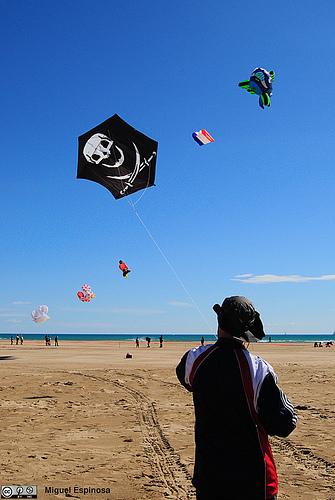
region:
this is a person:
[133, 262, 321, 498]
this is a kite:
[48, 95, 183, 219]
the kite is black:
[60, 93, 180, 217]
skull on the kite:
[65, 128, 141, 174]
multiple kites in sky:
[0, 13, 314, 366]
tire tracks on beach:
[63, 335, 331, 495]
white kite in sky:
[23, 292, 64, 329]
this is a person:
[154, 281, 318, 497]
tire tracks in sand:
[59, 354, 327, 497]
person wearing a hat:
[205, 274, 287, 359]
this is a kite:
[52, 90, 197, 240]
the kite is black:
[42, 97, 198, 236]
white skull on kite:
[77, 129, 127, 172]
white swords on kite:
[101, 136, 161, 194]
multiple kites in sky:
[32, 45, 306, 377]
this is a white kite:
[21, 296, 75, 351]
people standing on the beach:
[18, 319, 193, 360]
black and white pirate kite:
[76, 111, 159, 199]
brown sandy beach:
[0, 337, 333, 498]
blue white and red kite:
[190, 128, 214, 145]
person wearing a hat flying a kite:
[174, 294, 296, 498]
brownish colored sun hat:
[212, 294, 266, 343]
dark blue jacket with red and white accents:
[175, 335, 298, 497]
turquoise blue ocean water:
[0, 332, 334, 340]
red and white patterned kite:
[76, 282, 95, 302]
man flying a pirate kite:
[174, 294, 298, 498]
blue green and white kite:
[237, 65, 278, 109]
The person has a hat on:
[155, 274, 304, 382]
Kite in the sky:
[72, 283, 96, 304]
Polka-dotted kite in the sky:
[68, 280, 100, 307]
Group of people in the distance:
[6, 332, 27, 346]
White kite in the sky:
[27, 297, 54, 324]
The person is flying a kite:
[136, 234, 301, 462]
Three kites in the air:
[10, 256, 143, 328]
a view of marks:
[140, 429, 165, 458]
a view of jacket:
[173, 410, 247, 461]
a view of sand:
[120, 357, 174, 397]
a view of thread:
[144, 241, 190, 288]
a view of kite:
[71, 138, 172, 215]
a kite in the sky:
[237, 62, 281, 113]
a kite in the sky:
[116, 259, 134, 281]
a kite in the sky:
[72, 284, 92, 301]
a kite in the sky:
[28, 303, 46, 322]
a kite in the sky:
[191, 129, 198, 137]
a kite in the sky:
[62, 116, 162, 199]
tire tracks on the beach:
[58, 365, 319, 495]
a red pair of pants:
[193, 439, 274, 492]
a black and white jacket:
[172, 345, 291, 437]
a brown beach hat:
[209, 292, 267, 337]